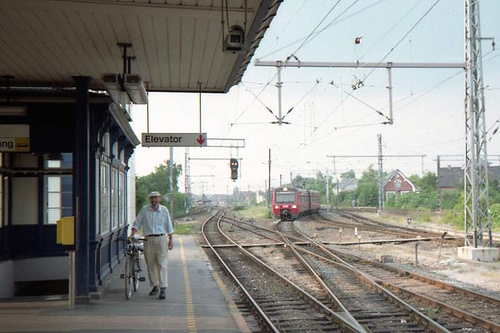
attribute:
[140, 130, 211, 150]
sign — white, elevator's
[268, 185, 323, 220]
train — red, coming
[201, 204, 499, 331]
tracks — brown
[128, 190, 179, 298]
man — standing, walking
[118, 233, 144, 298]
bike — man's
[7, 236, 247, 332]
platform — train's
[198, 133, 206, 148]
arrow — red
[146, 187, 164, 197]
hat — whiet, white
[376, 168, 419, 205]
house — white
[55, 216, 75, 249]
box — yellow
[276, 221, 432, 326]
train track — here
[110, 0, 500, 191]
sky — blue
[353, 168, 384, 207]
tree — green, big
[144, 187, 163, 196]
cap — white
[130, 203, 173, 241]
shirt — long sleeved, dress, white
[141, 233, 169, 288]
pants — tan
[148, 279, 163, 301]
shoes — pair, black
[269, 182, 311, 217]
engine — train's, red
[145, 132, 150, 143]
letter — e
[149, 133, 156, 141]
letter — l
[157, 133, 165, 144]
letter — v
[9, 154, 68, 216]
windows — open